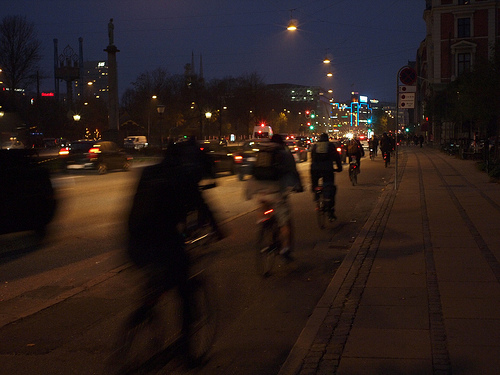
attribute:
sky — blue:
[122, 4, 390, 79]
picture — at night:
[5, 4, 495, 374]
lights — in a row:
[276, 14, 354, 110]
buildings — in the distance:
[242, 77, 427, 171]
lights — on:
[291, 54, 401, 145]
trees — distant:
[105, 56, 312, 141]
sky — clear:
[133, 4, 355, 72]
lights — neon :
[356, 104, 361, 125]